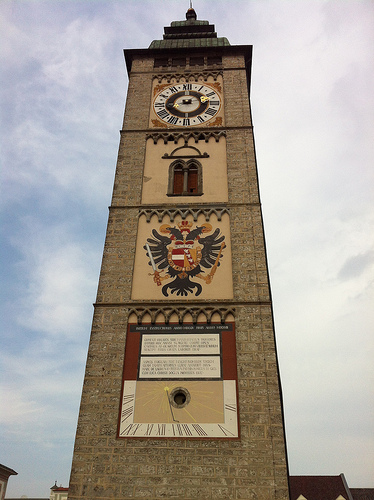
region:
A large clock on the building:
[153, 78, 227, 129]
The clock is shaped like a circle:
[152, 78, 223, 129]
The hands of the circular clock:
[166, 93, 210, 111]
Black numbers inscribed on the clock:
[168, 80, 208, 93]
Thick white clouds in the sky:
[291, 44, 369, 411]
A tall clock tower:
[68, 1, 289, 496]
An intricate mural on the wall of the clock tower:
[143, 218, 227, 300]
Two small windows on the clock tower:
[168, 155, 204, 200]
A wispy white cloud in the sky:
[7, 212, 93, 337]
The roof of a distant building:
[286, 469, 373, 498]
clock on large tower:
[156, 67, 218, 130]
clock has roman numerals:
[165, 84, 228, 128]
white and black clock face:
[151, 68, 198, 120]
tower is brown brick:
[116, 89, 252, 267]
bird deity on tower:
[138, 226, 227, 295]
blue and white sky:
[18, 117, 83, 226]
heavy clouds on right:
[255, 126, 359, 287]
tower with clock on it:
[64, 7, 306, 480]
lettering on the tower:
[143, 335, 230, 385]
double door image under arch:
[163, 161, 208, 193]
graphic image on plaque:
[115, 383, 250, 446]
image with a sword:
[139, 216, 226, 291]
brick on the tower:
[94, 455, 242, 481]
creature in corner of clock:
[209, 114, 225, 130]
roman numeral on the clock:
[180, 82, 194, 91]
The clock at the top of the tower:
[153, 78, 225, 124]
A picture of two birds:
[127, 214, 232, 302]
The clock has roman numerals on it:
[118, 390, 240, 448]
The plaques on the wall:
[127, 322, 234, 379]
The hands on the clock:
[163, 92, 219, 113]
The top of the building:
[117, 0, 258, 60]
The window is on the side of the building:
[161, 156, 207, 199]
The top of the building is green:
[146, 3, 234, 56]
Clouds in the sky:
[3, 210, 83, 348]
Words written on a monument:
[138, 330, 227, 383]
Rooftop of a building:
[290, 468, 356, 497]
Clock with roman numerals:
[152, 81, 225, 126]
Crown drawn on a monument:
[173, 218, 192, 236]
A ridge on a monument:
[93, 299, 276, 310]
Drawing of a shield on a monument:
[137, 220, 229, 296]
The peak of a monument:
[166, 0, 209, 24]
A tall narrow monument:
[67, 0, 291, 497]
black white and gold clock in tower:
[145, 77, 220, 132]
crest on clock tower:
[140, 219, 216, 299]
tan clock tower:
[109, 4, 290, 466]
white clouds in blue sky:
[29, 111, 62, 156]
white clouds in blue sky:
[296, 60, 331, 92]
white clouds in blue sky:
[36, 132, 63, 168]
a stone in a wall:
[69, 460, 97, 472]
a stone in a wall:
[93, 461, 114, 477]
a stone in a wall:
[113, 462, 140, 473]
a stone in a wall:
[142, 463, 163, 472]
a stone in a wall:
[167, 464, 191, 474]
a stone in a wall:
[193, 463, 212, 474]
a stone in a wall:
[215, 464, 233, 478]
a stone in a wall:
[237, 463, 258, 475]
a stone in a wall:
[255, 464, 288, 480]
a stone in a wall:
[256, 476, 291, 487]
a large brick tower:
[68, 1, 316, 497]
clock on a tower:
[146, 76, 232, 134]